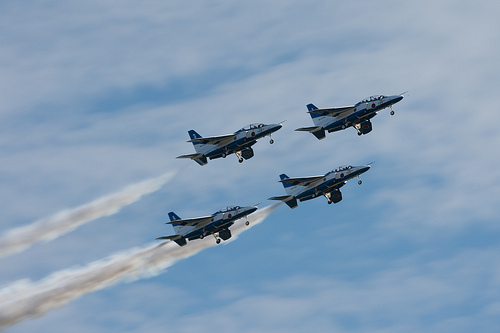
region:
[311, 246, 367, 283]
part of the sky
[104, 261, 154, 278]
smoke from the aeroplanes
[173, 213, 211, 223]
right wing of an aeroplane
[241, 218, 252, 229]
front wheel of an aeroplane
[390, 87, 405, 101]
front of a plane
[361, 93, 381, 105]
cockpit of a plane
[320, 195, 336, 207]
rare wheel of a plane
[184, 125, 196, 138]
part of a tail wing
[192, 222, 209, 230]
side of a plane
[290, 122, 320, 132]
part of a hind wing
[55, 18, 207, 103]
the sky is blue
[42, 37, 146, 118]
the sky is cloudy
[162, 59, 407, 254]
there are four planes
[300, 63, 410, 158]
the plane is flying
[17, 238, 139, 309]
the smoke is thick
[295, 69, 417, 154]
the plane is gray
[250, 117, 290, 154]
the plane has wheels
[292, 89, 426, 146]
the plane has a pilot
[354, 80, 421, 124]
the plane is pointy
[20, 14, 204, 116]
there are many clouds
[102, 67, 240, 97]
blue clouds trail in the sky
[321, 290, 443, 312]
soft white clouds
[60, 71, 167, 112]
over cast blue skies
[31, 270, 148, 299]
black dirt in smoke trails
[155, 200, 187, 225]
blue tail on plane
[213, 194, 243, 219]
glass in cockpit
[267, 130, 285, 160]
large tire in front of plane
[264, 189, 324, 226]
triangular tail on the Navy jet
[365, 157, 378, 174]
small nose of front of plane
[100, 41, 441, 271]
large cluster of blue navy jets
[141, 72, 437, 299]
fighter jets flying in formation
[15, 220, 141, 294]
white smoke coming out the engines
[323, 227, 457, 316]
a clear blue sky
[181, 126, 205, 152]
tail fin of the plane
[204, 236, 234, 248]
landing gear under the plane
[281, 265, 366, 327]
thin white clouds in the sky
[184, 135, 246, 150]
a wing on the side of the plane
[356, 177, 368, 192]
a black rubber wheel under the plane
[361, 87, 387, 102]
cockpit of the plane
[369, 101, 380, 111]
black gas cap cover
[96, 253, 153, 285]
smoke from the planes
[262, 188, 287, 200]
part of a hind wing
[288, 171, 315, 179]
right wing of a plane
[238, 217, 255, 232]
front wheel of the plane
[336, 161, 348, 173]
cockpit of the pilot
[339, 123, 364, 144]
rear wheels of the plane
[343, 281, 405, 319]
part of some clouds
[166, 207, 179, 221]
part of a tail wing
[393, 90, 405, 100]
tip of the plain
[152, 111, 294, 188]
military jet flying in formation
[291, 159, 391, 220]
military jet flying in formation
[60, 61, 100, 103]
white clouds in blue sky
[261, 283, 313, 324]
white clouds in blue sky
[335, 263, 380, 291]
white clouds in blue sky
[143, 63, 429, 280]
a group of jets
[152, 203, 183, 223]
tail on the jet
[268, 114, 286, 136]
nose of the jet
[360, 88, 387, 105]
seat of the jet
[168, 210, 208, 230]
wing on the jet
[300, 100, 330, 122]
the tail is blue